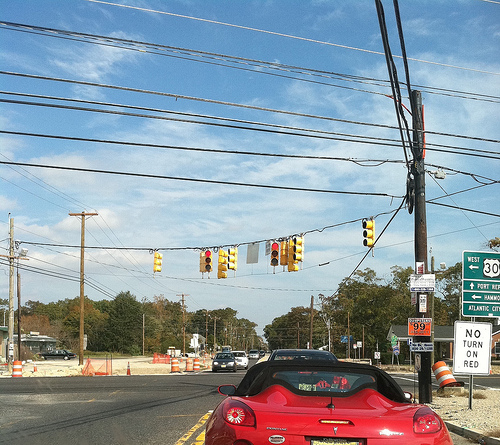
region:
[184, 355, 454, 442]
red car on the road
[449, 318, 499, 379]
black and white sign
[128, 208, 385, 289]
several traffic lights hanging on a wire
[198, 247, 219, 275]
traffic light shining red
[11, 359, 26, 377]
orange and white cone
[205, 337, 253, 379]
two cars stopped at a stoplight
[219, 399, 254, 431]
red light on the back of the vehicle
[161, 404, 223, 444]
yellow lines painted on the ground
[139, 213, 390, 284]
the traffic lights color yellow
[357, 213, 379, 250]
traffic light color yellow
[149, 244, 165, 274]
traffic light color yellow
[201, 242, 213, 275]
traffic light color yellow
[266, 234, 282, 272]
traffic light color yellow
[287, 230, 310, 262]
traffic light color yellow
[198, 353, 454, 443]
a red car on side the road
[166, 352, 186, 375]
cone is orange and white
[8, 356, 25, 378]
cone is orange and white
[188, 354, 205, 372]
cone is orange and white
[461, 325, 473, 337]
black letter on sign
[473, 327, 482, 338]
black letter on sign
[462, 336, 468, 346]
black letter on sign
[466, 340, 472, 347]
black letter on sign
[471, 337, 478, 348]
black letter on sign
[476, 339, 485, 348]
black letter on sign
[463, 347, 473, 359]
black letter on sign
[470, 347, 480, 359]
black letter on sign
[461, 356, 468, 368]
black letter on sign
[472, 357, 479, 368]
black letter on sign